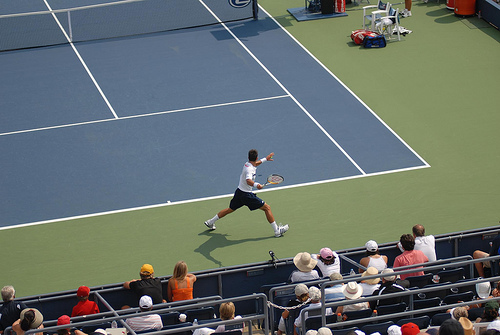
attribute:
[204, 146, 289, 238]
player — on court, tennis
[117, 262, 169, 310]
person — wearing orange hat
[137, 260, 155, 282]
hat — orange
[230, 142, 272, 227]
man — playing tennis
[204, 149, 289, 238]
man — ready, playing tennis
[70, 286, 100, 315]
person — wearing red shirt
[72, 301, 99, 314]
shirt — red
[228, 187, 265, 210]
shorts — black, on tennis player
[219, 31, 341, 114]
lines — white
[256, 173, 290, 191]
racquet — in man's hand, Tennis 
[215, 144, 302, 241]
player — on a court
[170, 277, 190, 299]
tanktop — orange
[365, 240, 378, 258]
cap — white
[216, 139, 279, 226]
man — holding tennis racket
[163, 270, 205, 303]
girl — wearing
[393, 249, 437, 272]
shirt — pink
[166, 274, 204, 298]
tank top — orange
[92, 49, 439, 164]
court — tennis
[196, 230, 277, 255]
shadow — man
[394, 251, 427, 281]
shirt — pink